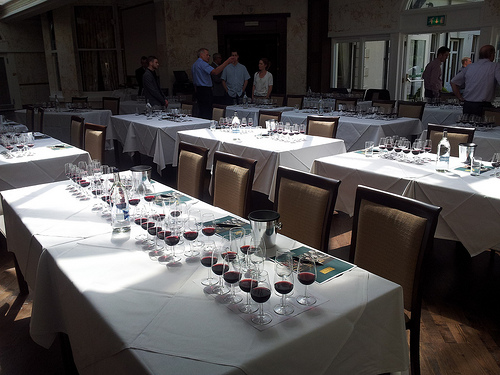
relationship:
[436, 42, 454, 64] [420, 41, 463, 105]
head of person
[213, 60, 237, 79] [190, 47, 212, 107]
arm of a person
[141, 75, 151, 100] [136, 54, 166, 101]
arm of a person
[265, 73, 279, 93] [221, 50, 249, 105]
arm of a man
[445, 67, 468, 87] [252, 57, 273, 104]
arm of a person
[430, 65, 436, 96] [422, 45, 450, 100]
arm of a person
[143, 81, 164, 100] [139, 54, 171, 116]
arm of a person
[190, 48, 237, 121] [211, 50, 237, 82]
man with extended arm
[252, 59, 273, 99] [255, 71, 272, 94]
person in shirt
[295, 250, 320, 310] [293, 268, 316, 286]
glass of wine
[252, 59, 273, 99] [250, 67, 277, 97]
person has shirt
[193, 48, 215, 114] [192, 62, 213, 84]
man has blue shirt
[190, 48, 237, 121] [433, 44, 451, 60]
man has hair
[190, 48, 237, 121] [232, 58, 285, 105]
man has shirt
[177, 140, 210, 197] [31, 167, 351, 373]
chair at table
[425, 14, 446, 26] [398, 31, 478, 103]
exit sign above door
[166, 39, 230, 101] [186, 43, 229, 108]
head of person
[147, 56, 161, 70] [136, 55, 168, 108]
head of person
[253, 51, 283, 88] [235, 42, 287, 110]
head of person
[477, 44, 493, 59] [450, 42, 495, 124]
head of person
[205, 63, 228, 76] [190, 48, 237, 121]
arm of man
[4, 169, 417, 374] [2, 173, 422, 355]
table covered in cloth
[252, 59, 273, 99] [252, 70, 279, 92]
person in shirt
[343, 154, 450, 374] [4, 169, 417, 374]
chair at table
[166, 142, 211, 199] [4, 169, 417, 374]
chair at table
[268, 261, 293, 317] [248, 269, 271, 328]
glass sitting glass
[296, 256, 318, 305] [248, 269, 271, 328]
glass waiting glass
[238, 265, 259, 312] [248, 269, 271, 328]
glass moving glass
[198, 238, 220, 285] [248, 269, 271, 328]
glass perching glass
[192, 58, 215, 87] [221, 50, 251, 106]
blue shirt worn man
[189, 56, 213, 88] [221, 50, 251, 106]
blue shirt fraying man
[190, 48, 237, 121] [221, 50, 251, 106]
man staring man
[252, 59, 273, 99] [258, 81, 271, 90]
person waiting shirt